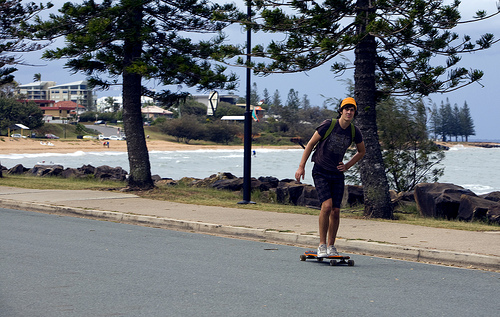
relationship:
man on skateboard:
[294, 94, 373, 258] [286, 253, 356, 264]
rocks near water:
[32, 164, 60, 176] [64, 155, 128, 168]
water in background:
[64, 155, 128, 168] [168, 155, 202, 179]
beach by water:
[27, 145, 72, 153] [64, 155, 128, 168]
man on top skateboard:
[294, 94, 373, 258] [286, 253, 356, 264]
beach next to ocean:
[27, 145, 72, 153] [151, 143, 304, 179]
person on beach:
[118, 125, 121, 137] [27, 145, 72, 153]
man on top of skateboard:
[294, 94, 373, 258] [286, 253, 356, 264]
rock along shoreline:
[456, 192, 499, 221] [394, 179, 500, 222]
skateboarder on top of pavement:
[294, 94, 373, 258] [381, 265, 499, 314]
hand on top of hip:
[339, 161, 348, 173] [335, 161, 350, 175]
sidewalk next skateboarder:
[99, 192, 278, 235] [294, 94, 373, 258]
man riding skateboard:
[294, 94, 373, 258] [286, 253, 356, 264]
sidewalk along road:
[99, 192, 278, 235] [14, 221, 283, 294]